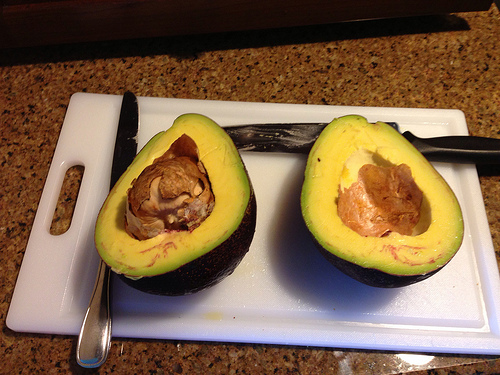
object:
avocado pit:
[125, 155, 217, 240]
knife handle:
[398, 126, 495, 166]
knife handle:
[73, 241, 113, 368]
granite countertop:
[2, 26, 499, 374]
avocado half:
[93, 112, 257, 297]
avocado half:
[299, 114, 465, 288]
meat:
[122, 134, 213, 241]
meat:
[334, 157, 427, 237]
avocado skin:
[119, 205, 257, 296]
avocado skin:
[306, 227, 448, 289]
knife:
[220, 121, 498, 164]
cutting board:
[3, 89, 496, 357]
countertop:
[0, 0, 499, 372]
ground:
[350, 60, 414, 101]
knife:
[72, 86, 137, 373]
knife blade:
[219, 118, 400, 158]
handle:
[402, 127, 499, 166]